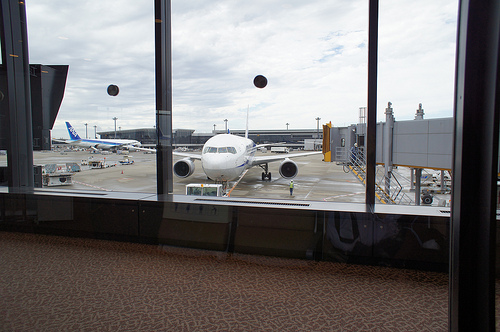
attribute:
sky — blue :
[31, 0, 458, 127]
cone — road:
[117, 167, 130, 186]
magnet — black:
[108, 85, 119, 95]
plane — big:
[188, 120, 252, 195]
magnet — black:
[6, 32, 28, 150]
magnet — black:
[251, 73, 268, 90]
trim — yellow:
[322, 123, 332, 163]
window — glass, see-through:
[25, 0, 156, 200]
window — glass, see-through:
[373, 0, 459, 205]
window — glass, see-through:
[0, 94, 6, 192]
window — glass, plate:
[375, 2, 456, 216]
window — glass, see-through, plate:
[166, 2, 367, 208]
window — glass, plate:
[14, 2, 163, 204]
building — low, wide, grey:
[98, 101, 385, 143]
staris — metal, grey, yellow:
[338, 150, 395, 190]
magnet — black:
[94, 78, 124, 108]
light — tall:
[107, 112, 124, 126]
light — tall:
[81, 116, 91, 129]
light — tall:
[88, 119, 107, 141]